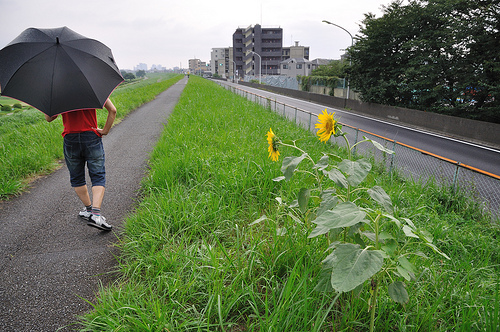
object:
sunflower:
[315, 109, 338, 142]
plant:
[308, 108, 388, 329]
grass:
[128, 241, 164, 328]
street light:
[247, 49, 264, 84]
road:
[207, 76, 499, 228]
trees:
[373, 0, 499, 113]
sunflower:
[264, 128, 282, 161]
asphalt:
[2, 223, 97, 330]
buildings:
[274, 42, 309, 87]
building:
[230, 24, 283, 86]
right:
[203, 23, 456, 186]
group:
[198, 19, 315, 80]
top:
[352, 13, 479, 34]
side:
[301, 19, 416, 179]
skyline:
[128, 60, 182, 76]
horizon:
[126, 18, 420, 68]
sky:
[37, 6, 433, 61]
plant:
[265, 127, 330, 225]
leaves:
[324, 238, 390, 295]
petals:
[320, 137, 330, 144]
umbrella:
[0, 23, 126, 116]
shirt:
[60, 115, 104, 137]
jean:
[58, 131, 106, 189]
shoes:
[86, 213, 112, 231]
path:
[0, 71, 186, 331]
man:
[40, 45, 116, 235]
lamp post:
[323, 19, 353, 99]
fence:
[196, 71, 499, 231]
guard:
[204, 73, 499, 150]